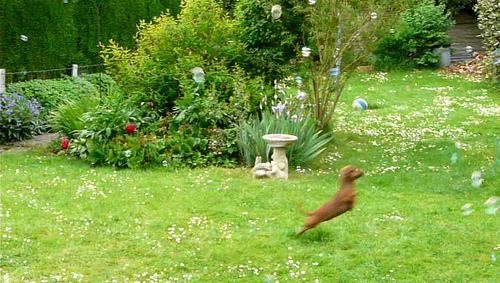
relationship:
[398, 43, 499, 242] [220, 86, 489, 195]
bubbles in air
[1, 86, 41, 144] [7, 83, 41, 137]
bush with flowers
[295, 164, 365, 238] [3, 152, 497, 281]
dog playing in a yard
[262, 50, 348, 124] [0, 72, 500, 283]
section of flowers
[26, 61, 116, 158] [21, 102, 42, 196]
row of bushes on left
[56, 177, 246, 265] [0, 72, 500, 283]
grass has patches of flowers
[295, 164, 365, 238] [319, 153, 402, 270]
dog leaping in air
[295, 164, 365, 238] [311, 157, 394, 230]
dog leaping in air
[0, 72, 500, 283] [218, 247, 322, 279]
flowers in grass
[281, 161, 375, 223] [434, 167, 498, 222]
dog chasing bubbles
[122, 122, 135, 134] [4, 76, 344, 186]
blossom in garden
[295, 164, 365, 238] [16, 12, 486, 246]
dog jumping in air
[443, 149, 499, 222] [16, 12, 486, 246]
bubbles bubbling in air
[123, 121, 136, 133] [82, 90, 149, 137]
red flower on leaves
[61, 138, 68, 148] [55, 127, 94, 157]
red flower on leaves